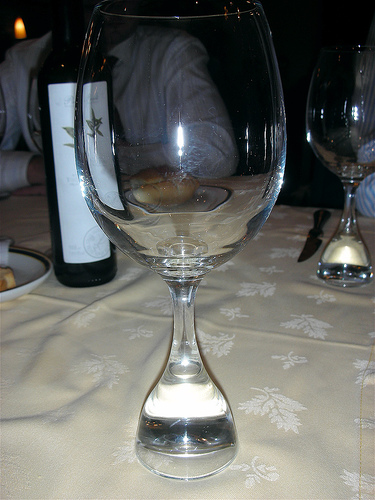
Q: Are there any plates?
A: Yes, there is a plate.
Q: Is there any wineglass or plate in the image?
A: Yes, there is a plate.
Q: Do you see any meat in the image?
A: No, there is no meat.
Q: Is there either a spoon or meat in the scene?
A: No, there are no meat or spoons.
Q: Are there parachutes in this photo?
A: No, there are no parachutes.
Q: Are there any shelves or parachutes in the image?
A: No, there are no parachutes or shelves.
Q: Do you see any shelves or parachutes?
A: No, there are no parachutes or shelves.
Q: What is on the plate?
A: The roll is on the plate.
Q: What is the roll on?
A: The roll is on the plate.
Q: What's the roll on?
A: The roll is on the plate.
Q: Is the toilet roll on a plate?
A: Yes, the toilet roll is on a plate.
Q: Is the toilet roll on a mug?
A: No, the toilet roll is on a plate.